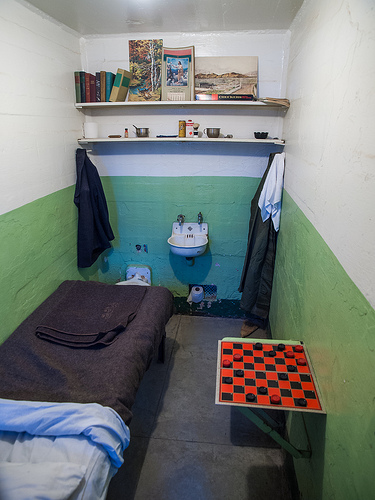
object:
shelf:
[75, 99, 293, 107]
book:
[111, 69, 126, 102]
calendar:
[161, 45, 194, 102]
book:
[105, 70, 110, 102]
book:
[85, 71, 91, 104]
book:
[79, 70, 84, 105]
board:
[217, 333, 321, 412]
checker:
[269, 392, 282, 406]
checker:
[254, 341, 265, 351]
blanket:
[37, 277, 149, 351]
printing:
[100, 298, 120, 325]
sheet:
[0, 397, 135, 469]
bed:
[1, 278, 177, 497]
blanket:
[2, 277, 178, 421]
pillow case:
[1, 463, 89, 499]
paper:
[188, 285, 203, 306]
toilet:
[112, 263, 153, 286]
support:
[234, 404, 311, 459]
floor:
[165, 314, 297, 499]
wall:
[269, 1, 374, 497]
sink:
[167, 220, 211, 259]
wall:
[78, 28, 293, 302]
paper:
[82, 119, 96, 139]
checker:
[220, 358, 233, 369]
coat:
[237, 153, 284, 327]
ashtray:
[253, 132, 269, 137]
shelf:
[79, 137, 288, 145]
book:
[99, 70, 106, 104]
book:
[96, 70, 101, 101]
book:
[79, 70, 85, 102]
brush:
[222, 131, 234, 141]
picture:
[128, 38, 162, 102]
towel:
[258, 151, 284, 231]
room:
[1, 1, 372, 499]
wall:
[2, 0, 100, 343]